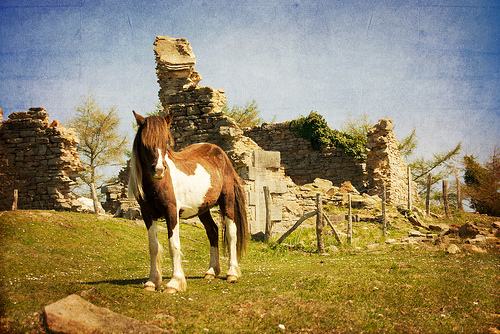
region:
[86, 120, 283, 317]
A pony is on a field.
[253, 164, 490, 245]
A fence surrounds a rock wall.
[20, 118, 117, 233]
A rock wall is crumbling on a field.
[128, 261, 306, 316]
Grass surrounds a pony.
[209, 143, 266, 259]
A pony has a brown tail.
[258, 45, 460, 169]
Clear skies hovering above a field.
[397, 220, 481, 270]
Rocks are displayed next to a fence.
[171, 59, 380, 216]
A crumbling building is standing behind a pony.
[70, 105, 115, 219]
A tree is behind a rock wall.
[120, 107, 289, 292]
A pony is in front of a rock wall.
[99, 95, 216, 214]
the horse is looking down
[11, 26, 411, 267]
the stone house is ruined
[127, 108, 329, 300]
a brown and white horse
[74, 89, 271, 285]
a brown and white horse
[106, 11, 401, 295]
a ruined stone house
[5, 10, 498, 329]
Exterior shot, daytime, probably taken in spring, or summer.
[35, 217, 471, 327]
Short grass and rocks on lightly rolling terrain.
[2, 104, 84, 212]
Remains of rustic, rockwall with opening.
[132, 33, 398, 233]
Remains of small, cottage-type dwelling, made of rock and wood.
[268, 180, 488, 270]
Remains of fencing and piles of detritus.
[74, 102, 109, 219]
Young tree with sparse leaves, in distance.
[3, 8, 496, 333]
Rural view, showing architectural remains and farm animal.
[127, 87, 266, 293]
Lone, brown and white horse, standing on grass.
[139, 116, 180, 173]
Shaggy hair, obstructing young horse's face.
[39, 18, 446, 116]
Clear, blue and white sky.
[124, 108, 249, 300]
The pony is brown and white.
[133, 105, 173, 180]
The pony has a brown mane.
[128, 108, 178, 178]
The mane is long on the pony.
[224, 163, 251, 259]
The tail on the pony is brown.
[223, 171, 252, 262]
The tail on the pony is long.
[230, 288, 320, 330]
The grass in the forefront is green.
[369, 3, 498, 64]
The sky is blue in color.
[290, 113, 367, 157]
The plant on the building is green.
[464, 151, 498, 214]
The bush on the right is brown.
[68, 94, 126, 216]
The tree in the background is small.